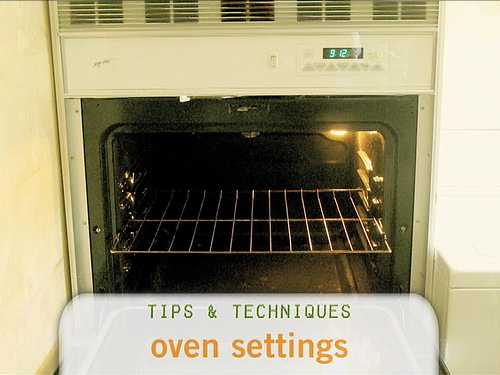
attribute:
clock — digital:
[319, 43, 366, 60]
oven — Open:
[56, 15, 459, 370]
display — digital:
[318, 44, 366, 63]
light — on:
[235, 128, 262, 145]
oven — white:
[50, 27, 437, 338]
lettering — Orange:
[135, 330, 350, 367]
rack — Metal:
[73, 87, 359, 297]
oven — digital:
[36, 30, 438, 373]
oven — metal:
[64, 35, 419, 301]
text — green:
[134, 294, 416, 345]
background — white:
[58, 288, 443, 373]